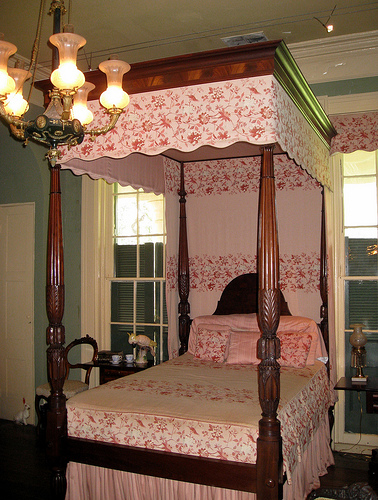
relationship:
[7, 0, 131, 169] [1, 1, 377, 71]
chandelier hanging from ceiling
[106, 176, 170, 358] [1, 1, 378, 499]
window in room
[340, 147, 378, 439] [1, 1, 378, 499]
window in room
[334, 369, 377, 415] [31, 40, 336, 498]
table beside bed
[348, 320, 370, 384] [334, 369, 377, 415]
lamp on table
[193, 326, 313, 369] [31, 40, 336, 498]
pillows on bed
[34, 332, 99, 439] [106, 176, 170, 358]
chair next to window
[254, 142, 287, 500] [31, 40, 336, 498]
post on bed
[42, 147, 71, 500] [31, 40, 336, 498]
post on bed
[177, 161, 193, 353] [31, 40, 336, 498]
post on bed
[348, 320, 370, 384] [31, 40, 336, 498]
lamp beside bed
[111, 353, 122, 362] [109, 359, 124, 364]
teacup in saucer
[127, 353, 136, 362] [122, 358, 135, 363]
teacup in saucer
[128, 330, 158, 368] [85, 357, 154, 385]
bird on table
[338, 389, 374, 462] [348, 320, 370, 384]
cord on lamp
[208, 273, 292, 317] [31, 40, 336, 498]
headboard on bed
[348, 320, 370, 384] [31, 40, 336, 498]
lamp next to bed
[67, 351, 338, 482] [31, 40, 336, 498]
bedspread on bed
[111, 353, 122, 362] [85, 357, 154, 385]
teacup on table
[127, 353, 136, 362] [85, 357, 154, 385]
teacup on table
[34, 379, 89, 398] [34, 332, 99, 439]
seat on chair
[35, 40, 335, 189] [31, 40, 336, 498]
canopy on bed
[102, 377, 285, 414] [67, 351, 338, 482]
flowers on bedspread